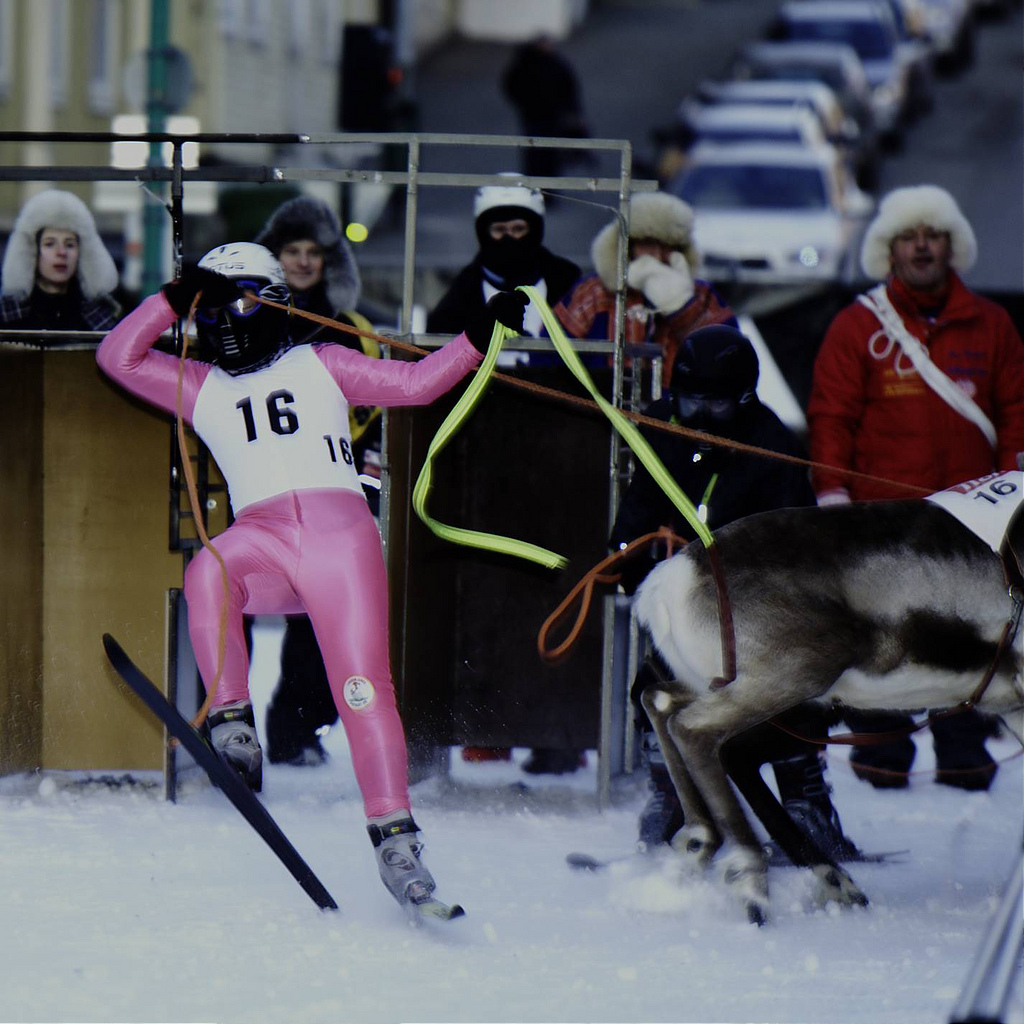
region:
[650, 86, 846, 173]
a car in a parking lot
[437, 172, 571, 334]
a person walking on a sidewalk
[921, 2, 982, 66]
a car in a parking lot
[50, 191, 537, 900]
a person walking on the ice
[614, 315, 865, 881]
a person walking on the ice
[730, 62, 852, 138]
a vehicle on the road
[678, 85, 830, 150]
a vehicle on the road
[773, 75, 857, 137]
a vehicle on the road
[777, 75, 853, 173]
a vehicle on the road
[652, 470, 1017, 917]
a dog on a leach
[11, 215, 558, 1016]
a person on the snow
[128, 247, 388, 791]
a person wearing a suit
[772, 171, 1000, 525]
a person wearing a jacket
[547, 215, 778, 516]
a person wearing a jacket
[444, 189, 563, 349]
a person wearing a jacket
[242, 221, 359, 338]
a person wearing a jacket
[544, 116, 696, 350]
a person wearing a hat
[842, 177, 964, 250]
the hat of a man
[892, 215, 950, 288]
the face of a man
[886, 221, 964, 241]
the eyes of a man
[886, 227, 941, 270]
the nose of a man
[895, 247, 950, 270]
the mouth of a man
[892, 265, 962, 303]
the chin of a man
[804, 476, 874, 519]
the hand of a man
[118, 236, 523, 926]
Skier in pink ski suit.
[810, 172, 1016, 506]
Man in red coat and white fur hat.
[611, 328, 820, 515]
Person in black helmet and black coat.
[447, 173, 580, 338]
Person in white helmet and black face mask.